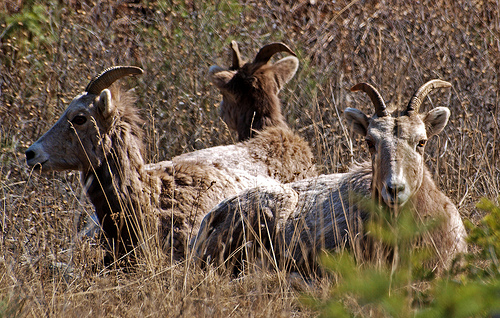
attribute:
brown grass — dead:
[2, 1, 497, 316]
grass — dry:
[7, 15, 467, 289]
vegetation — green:
[324, 220, 486, 315]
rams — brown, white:
[18, 27, 485, 289]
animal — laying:
[25, 63, 315, 280]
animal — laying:
[211, 37, 299, 142]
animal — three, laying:
[188, 78, 470, 296]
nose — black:
[386, 181, 405, 196]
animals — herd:
[23, 46, 470, 281]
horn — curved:
[349, 79, 388, 113]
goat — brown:
[186, 76, 470, 292]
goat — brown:
[208, 40, 298, 137]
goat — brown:
[23, 64, 315, 276]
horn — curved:
[406, 77, 452, 113]